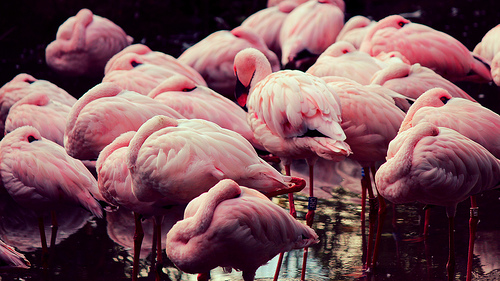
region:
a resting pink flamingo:
[163, 178, 321, 278]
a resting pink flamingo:
[125, 115, 306, 279]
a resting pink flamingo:
[98, 131, 164, 278]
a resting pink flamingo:
[0, 125, 118, 278]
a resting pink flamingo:
[65, 83, 183, 166]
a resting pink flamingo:
[4, 93, 70, 149]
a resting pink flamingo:
[1, 72, 76, 110]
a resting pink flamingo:
[45, 5, 137, 72]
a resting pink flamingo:
[173, 24, 282, 80]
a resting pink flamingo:
[233, 46, 351, 278]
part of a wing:
[266, 223, 286, 250]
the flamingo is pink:
[215, 38, 322, 165]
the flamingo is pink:
[386, 120, 492, 190]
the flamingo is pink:
[133, 149, 317, 271]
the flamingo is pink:
[77, 95, 224, 164]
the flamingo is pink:
[59, 64, 181, 156]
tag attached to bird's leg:
[302, 189, 322, 214]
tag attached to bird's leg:
[337, 164, 371, 182]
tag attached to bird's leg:
[375, 210, 405, 249]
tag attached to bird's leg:
[457, 197, 486, 239]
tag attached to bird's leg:
[294, 170, 328, 221]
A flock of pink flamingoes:
[16, 14, 444, 188]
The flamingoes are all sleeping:
[33, 6, 162, 226]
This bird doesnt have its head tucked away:
[232, 44, 269, 98]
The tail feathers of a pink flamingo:
[285, 79, 343, 154]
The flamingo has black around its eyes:
[230, 64, 244, 86]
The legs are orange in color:
[278, 159, 315, 227]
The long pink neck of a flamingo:
[178, 168, 220, 256]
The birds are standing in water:
[286, 176, 391, 266]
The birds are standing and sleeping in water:
[260, 4, 467, 236]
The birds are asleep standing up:
[101, 39, 278, 253]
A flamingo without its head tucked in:
[231, 45, 351, 279]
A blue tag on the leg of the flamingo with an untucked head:
[306, 193, 319, 209]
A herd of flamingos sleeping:
[1, 0, 499, 280]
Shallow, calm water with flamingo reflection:
[0, 110, 495, 280]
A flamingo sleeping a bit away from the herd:
[44, 8, 132, 75]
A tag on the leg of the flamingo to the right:
[468, 203, 480, 218]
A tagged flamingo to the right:
[373, 124, 499, 279]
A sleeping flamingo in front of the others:
[164, 178, 319, 280]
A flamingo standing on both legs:
[230, 45, 352, 279]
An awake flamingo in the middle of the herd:
[228, 47, 353, 279]